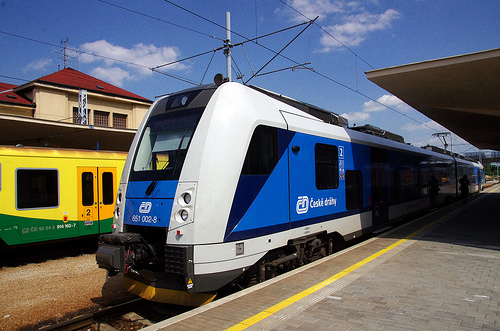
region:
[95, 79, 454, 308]
a white and blue train engine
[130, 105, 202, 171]
a train front windshield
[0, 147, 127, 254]
a yellow and green passenger car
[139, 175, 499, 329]
a train boarding platform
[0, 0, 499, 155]
a blue cloudy sky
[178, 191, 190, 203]
a train front headlight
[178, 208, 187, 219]
a train front headlight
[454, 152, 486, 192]
a blue and white train car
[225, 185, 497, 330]
a long yellow line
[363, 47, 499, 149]
a passenger overhead shelter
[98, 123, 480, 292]
blue and white train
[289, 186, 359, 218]
white name on train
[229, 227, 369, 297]
black wheels on train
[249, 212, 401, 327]
yellow line on platform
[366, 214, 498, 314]
grey bricks on platform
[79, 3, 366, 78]
blue and white sky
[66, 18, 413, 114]
small clouds in sky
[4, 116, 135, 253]
green and yellow train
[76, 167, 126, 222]
orange doors on train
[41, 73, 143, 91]
red roof above train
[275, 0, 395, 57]
Clouds in the sky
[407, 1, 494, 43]
Part of the sky is clear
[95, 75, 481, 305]
Train arriving at the station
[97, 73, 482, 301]
Train is white and blue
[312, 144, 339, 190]
The window is dark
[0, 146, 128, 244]
Yellow and green train car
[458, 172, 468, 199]
Someone is walking away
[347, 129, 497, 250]
Shadow cast by roof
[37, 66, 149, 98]
The roof is red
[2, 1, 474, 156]
Wires hanging over the train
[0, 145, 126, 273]
yellow, orange and green train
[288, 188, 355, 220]
logo and company on side of train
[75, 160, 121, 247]
orange and green train doors with the number two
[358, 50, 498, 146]
overhang for train platform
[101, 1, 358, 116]
electrical wires for the train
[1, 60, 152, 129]
top of a building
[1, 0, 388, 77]
partially cloudy blue sky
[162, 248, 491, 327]
brick and concrete train platform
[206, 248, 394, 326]
yellow stripe on train platform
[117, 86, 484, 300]
blue and white light rail train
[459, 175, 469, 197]
person walking on the train platform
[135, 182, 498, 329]
brick train platform with yellow line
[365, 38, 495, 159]
roof over train platform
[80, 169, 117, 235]
yellow door with the number 2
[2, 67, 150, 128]
building with the red roof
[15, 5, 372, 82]
power lines above the train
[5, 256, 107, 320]
brown dirt between the two trains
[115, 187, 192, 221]
front head lights on blue and white train